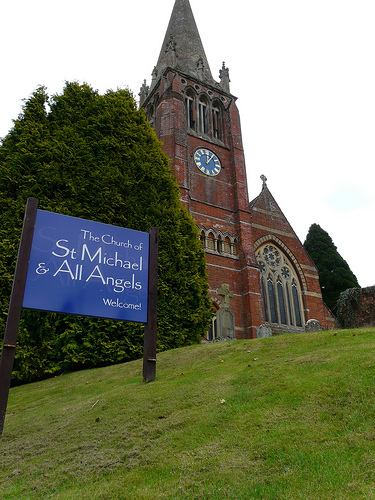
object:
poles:
[0, 197, 39, 427]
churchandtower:
[138, 0, 266, 339]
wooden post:
[142, 228, 158, 382]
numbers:
[215, 164, 220, 168]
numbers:
[214, 168, 220, 173]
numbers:
[206, 169, 210, 175]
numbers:
[201, 150, 205, 155]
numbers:
[196, 151, 201, 156]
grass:
[0, 328, 375, 498]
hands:
[206, 153, 214, 164]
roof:
[142, 0, 236, 100]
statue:
[164, 35, 178, 68]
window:
[207, 229, 214, 250]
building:
[137, 0, 338, 341]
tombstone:
[216, 284, 236, 340]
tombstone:
[257, 319, 273, 337]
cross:
[260, 174, 268, 185]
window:
[216, 230, 223, 255]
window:
[267, 271, 280, 324]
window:
[291, 278, 303, 328]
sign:
[20, 207, 149, 329]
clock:
[193, 146, 222, 177]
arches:
[182, 85, 199, 95]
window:
[224, 232, 231, 254]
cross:
[217, 284, 234, 306]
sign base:
[0, 316, 157, 436]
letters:
[107, 277, 115, 285]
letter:
[52, 239, 70, 258]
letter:
[70, 248, 77, 260]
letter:
[81, 244, 102, 264]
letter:
[53, 258, 75, 280]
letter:
[86, 265, 107, 285]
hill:
[1, 326, 373, 499]